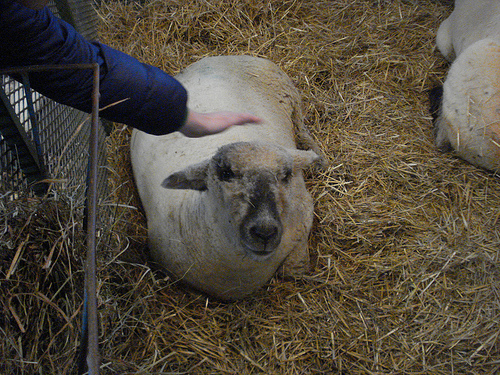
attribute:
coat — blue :
[15, 19, 231, 151]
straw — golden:
[343, 193, 476, 307]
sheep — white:
[123, 37, 406, 309]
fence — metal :
[6, 61, 106, 373]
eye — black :
[219, 163, 238, 188]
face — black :
[217, 157, 297, 253]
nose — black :
[251, 218, 277, 242]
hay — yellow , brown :
[295, 15, 470, 372]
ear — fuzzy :
[159, 158, 208, 190]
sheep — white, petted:
[127, 53, 323, 300]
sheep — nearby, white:
[119, 39, 335, 304]